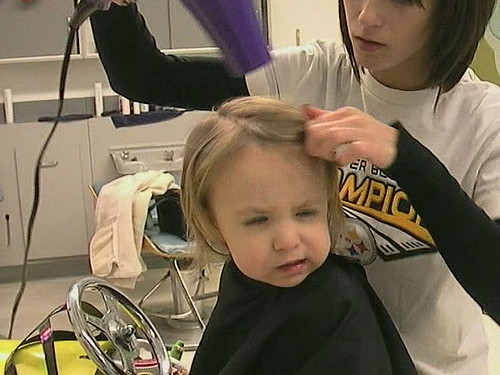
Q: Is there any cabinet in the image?
A: Yes, there is a cabinet.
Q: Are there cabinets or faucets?
A: Yes, there is a cabinet.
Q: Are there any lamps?
A: No, there are no lamps.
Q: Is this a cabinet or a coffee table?
A: This is a cabinet.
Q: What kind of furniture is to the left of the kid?
A: The piece of furniture is a cabinet.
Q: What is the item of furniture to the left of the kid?
A: The piece of furniture is a cabinet.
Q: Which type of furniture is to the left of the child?
A: The piece of furniture is a cabinet.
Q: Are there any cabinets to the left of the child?
A: Yes, there is a cabinet to the left of the child.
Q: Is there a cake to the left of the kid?
A: No, there is a cabinet to the left of the kid.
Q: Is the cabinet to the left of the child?
A: Yes, the cabinet is to the left of the child.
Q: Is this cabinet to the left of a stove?
A: No, the cabinet is to the left of the child.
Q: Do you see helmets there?
A: No, there are no helmets.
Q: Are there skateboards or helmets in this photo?
A: No, there are no helmets or skateboards.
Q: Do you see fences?
A: No, there are no fences.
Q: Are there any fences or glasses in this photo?
A: No, there are no fences or glasses.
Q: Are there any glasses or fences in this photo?
A: No, there are no fences or glasses.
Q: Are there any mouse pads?
A: No, there are no mouse pads.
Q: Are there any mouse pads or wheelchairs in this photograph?
A: No, there are no mouse pads or wheelchairs.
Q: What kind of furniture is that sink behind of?
A: The sink is behind the chair.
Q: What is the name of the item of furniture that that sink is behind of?
A: The piece of furniture is a chair.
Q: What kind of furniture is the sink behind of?
A: The sink is behind the chair.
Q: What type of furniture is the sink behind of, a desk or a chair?
A: The sink is behind a chair.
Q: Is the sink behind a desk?
A: No, the sink is behind the chair.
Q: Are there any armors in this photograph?
A: No, there are no armors.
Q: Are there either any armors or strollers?
A: No, there are no armors or strollers.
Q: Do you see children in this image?
A: Yes, there is a child.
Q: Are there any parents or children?
A: Yes, there is a child.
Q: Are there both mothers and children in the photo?
A: No, there is a child but no mothers.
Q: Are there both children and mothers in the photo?
A: No, there is a child but no mothers.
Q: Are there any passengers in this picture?
A: No, there are no passengers.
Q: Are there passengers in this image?
A: No, there are no passengers.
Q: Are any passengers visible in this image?
A: No, there are no passengers.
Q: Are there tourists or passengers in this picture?
A: No, there are no passengers or tourists.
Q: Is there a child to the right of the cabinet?
A: Yes, there is a child to the right of the cabinet.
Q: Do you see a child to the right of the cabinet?
A: Yes, there is a child to the right of the cabinet.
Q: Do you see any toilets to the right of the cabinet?
A: No, there is a child to the right of the cabinet.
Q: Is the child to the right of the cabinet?
A: Yes, the child is to the right of the cabinet.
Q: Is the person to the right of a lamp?
A: No, the kid is to the right of the cabinet.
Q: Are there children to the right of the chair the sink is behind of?
A: Yes, there is a child to the right of the chair.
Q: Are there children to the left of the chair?
A: No, the child is to the right of the chair.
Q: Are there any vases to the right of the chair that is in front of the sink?
A: No, there is a child to the right of the chair.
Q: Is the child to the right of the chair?
A: Yes, the child is to the right of the chair.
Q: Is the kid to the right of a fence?
A: No, the kid is to the right of the chair.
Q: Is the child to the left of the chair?
A: No, the child is to the right of the chair.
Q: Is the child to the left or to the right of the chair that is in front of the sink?
A: The child is to the right of the chair.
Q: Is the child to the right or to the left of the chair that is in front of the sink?
A: The child is to the right of the chair.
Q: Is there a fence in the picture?
A: No, there are no fences.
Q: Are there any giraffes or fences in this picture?
A: No, there are no fences or giraffes.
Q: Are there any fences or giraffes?
A: No, there are no fences or giraffes.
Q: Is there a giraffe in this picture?
A: No, there are no giraffes.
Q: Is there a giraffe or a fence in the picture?
A: No, there are no giraffes or fences.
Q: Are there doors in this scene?
A: Yes, there is a door.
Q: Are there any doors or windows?
A: Yes, there is a door.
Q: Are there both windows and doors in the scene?
A: No, there is a door but no windows.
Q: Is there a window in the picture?
A: No, there are no windows.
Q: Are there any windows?
A: No, there are no windows.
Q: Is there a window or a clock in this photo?
A: No, there are no windows or clocks.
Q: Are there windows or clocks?
A: No, there are no windows or clocks.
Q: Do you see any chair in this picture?
A: Yes, there is a chair.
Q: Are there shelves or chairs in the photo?
A: Yes, there is a chair.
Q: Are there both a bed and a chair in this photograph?
A: No, there is a chair but no beds.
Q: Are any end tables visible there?
A: No, there are no end tables.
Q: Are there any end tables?
A: No, there are no end tables.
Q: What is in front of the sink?
A: The chair is in front of the sink.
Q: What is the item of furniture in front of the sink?
A: The piece of furniture is a chair.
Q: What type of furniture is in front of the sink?
A: The piece of furniture is a chair.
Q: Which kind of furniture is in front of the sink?
A: The piece of furniture is a chair.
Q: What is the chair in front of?
A: The chair is in front of the sink.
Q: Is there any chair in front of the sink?
A: Yes, there is a chair in front of the sink.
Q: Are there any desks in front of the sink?
A: No, there is a chair in front of the sink.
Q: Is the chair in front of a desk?
A: No, the chair is in front of a sink.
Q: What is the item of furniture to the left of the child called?
A: The piece of furniture is a chair.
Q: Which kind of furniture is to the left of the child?
A: The piece of furniture is a chair.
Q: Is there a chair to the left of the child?
A: Yes, there is a chair to the left of the child.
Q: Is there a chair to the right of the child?
A: No, the chair is to the left of the child.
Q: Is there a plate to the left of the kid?
A: No, there is a chair to the left of the kid.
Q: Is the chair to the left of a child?
A: Yes, the chair is to the left of a child.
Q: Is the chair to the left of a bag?
A: No, the chair is to the left of a child.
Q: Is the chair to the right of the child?
A: No, the chair is to the left of the child.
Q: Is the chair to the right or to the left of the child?
A: The chair is to the left of the child.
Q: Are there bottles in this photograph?
A: Yes, there is a bottle.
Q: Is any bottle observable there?
A: Yes, there is a bottle.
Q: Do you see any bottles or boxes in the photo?
A: Yes, there is a bottle.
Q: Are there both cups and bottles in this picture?
A: No, there is a bottle but no cups.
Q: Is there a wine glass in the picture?
A: No, there are no wine glasses.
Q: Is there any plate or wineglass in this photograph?
A: No, there are no wine glasses or plates.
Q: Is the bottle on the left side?
A: Yes, the bottle is on the left of the image.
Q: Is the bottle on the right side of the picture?
A: No, the bottle is on the left of the image.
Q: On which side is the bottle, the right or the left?
A: The bottle is on the left of the image.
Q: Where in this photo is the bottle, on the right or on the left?
A: The bottle is on the left of the image.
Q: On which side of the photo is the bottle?
A: The bottle is on the left of the image.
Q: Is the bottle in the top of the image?
A: Yes, the bottle is in the top of the image.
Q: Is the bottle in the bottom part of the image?
A: No, the bottle is in the top of the image.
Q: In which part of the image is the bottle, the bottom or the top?
A: The bottle is in the top of the image.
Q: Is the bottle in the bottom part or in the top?
A: The bottle is in the top of the image.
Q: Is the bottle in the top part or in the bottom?
A: The bottle is in the top of the image.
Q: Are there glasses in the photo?
A: No, there are no glasses.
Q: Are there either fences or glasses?
A: No, there are no glasses or fences.